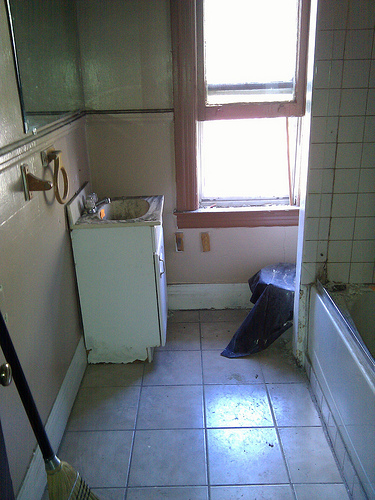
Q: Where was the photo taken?
A: Bathroom.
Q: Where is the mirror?
A: Above the sink.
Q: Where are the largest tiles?
A: On ground.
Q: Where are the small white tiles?
A: Shower.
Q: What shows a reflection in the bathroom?
A: A mirror.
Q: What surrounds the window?
A: A pink frame.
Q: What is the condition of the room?
A: Dirty.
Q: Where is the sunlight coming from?
A: Open window.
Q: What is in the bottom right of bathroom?
A: A tub.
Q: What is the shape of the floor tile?
A: Square.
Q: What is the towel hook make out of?
A: Wood.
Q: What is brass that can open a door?
A: A knob.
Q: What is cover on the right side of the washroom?
A: Toilet with black cover on it.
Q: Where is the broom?
A: On bathroom floor.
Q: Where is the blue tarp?
A: Over the toilet seat.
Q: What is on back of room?
A: Open window.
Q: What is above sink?
A: Corner mirror.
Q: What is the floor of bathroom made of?
A: Tiles.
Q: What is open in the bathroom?
A: Window.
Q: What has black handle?
A: Broom.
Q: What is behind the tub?
A: Tiled wall.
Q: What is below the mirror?
A: Sink.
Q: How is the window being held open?
A: Stick.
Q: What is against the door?
A: Broom.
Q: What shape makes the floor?
A: Squares.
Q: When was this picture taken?
A: Daytime.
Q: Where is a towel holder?
A: Wall above sink.